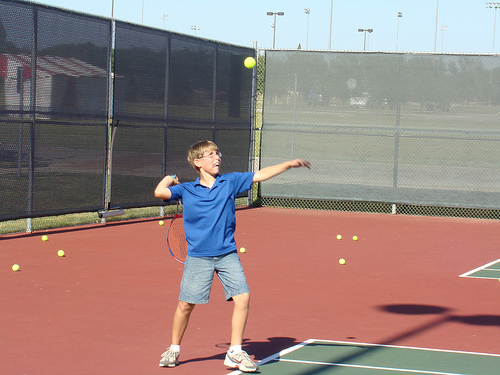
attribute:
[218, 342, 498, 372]
floor — green 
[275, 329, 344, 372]
lines — white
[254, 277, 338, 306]
clay — red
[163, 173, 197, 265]
racket — blue 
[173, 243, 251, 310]
blue shorts — jeans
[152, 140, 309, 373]
boy — young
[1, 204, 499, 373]
claycourt — clay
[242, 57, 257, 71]
yellow ball — flying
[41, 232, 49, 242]
tennis ball — yellow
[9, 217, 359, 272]
balls — yellow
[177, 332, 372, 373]
shadow — boy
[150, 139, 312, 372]
young boy — playing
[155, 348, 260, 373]
sneakers —  white 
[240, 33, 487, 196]
netting — black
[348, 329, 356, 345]
shadow — tennis ball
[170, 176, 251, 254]
shirt — blue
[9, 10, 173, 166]
screen — black